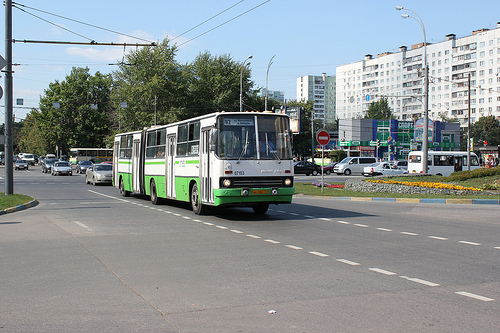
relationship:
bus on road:
[84, 95, 310, 237] [6, 166, 499, 321]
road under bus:
[6, 166, 499, 321] [84, 95, 310, 237]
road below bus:
[6, 166, 499, 321] [84, 95, 310, 237]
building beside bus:
[294, 26, 499, 153] [84, 95, 310, 237]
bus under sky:
[84, 95, 310, 237] [2, 1, 490, 101]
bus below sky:
[84, 95, 310, 237] [2, 1, 490, 101]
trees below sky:
[22, 46, 280, 167] [2, 1, 490, 101]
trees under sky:
[22, 46, 280, 167] [2, 1, 490, 101]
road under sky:
[6, 166, 499, 321] [2, 1, 490, 101]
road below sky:
[6, 166, 499, 321] [2, 1, 490, 101]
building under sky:
[294, 26, 499, 153] [2, 1, 490, 101]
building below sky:
[294, 26, 499, 153] [2, 1, 490, 101]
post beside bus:
[3, 1, 25, 193] [84, 95, 310, 237]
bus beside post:
[84, 95, 310, 237] [3, 1, 25, 193]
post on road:
[3, 1, 25, 193] [6, 166, 499, 321]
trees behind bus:
[14, 42, 310, 121] [107, 102, 301, 224]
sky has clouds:
[5, 3, 498, 123] [61, 24, 186, 68]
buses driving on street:
[63, 105, 300, 230] [6, 155, 498, 328]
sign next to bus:
[312, 122, 336, 197] [84, 95, 310, 237]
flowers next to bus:
[316, 168, 493, 200] [84, 95, 310, 237]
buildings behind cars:
[287, 51, 498, 190] [16, 113, 498, 236]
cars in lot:
[294, 139, 487, 179] [280, 135, 494, 195]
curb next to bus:
[292, 180, 499, 216] [107, 102, 301, 224]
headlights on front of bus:
[214, 171, 300, 186] [107, 102, 301, 224]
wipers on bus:
[224, 127, 296, 167] [107, 102, 301, 224]